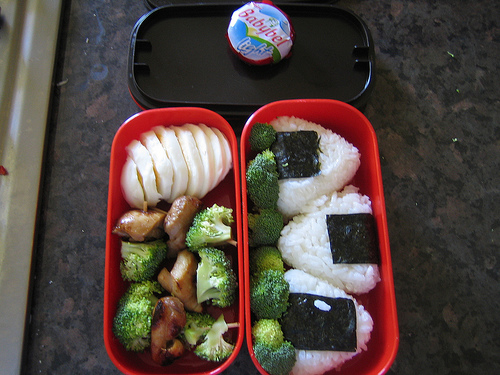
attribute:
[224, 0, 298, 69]
cheese — babybel, light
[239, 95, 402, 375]
container — red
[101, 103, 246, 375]
container — red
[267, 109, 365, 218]
rice — steamed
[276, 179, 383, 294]
rice — steamed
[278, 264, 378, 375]
rice — steamed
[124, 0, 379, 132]
lid — black